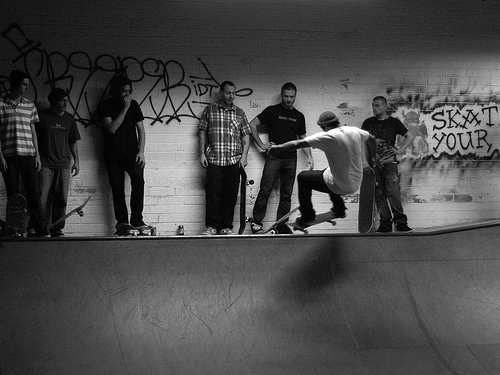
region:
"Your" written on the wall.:
[424, 127, 485, 159]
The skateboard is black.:
[319, 209, 362, 224]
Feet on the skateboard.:
[291, 207, 350, 224]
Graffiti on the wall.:
[140, 69, 209, 118]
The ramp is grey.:
[204, 301, 282, 336]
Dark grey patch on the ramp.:
[466, 343, 496, 374]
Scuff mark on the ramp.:
[188, 279, 259, 336]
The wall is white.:
[152, 153, 192, 192]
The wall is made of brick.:
[152, 187, 201, 221]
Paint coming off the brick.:
[62, 176, 109, 205]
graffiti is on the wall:
[0, 0, 251, 146]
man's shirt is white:
[296, 120, 391, 205]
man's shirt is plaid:
[200, 97, 256, 162]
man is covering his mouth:
[91, 65, 141, 141]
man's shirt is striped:
[0, 96, 45, 151]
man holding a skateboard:
[190, 67, 255, 237]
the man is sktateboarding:
[276, 100, 377, 225]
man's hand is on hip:
[360, 96, 425, 161]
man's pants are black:
[286, 160, 346, 220]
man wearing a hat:
[306, 107, 336, 135]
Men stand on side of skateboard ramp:
[10, 69, 497, 267]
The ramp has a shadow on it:
[275, 227, 366, 311]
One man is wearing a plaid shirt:
[193, 77, 248, 183]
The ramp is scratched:
[45, 252, 324, 322]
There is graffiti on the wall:
[405, 72, 497, 197]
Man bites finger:
[81, 60, 198, 245]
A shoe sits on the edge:
[172, 218, 187, 241]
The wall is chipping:
[288, 47, 385, 110]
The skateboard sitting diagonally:
[42, 182, 99, 237]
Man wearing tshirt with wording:
[260, 95, 329, 203]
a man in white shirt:
[274, 87, 394, 248]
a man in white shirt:
[280, 125, 333, 191]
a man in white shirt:
[264, 52, 413, 353]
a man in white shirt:
[308, 91, 391, 351]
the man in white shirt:
[282, 114, 394, 263]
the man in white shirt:
[286, 28, 419, 315]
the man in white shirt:
[271, 71, 363, 298]